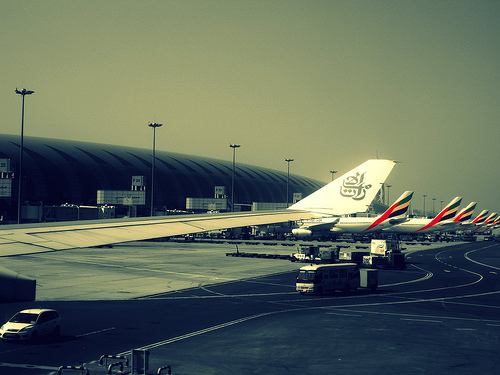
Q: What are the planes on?
A: The tarmac.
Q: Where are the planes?
A: The airport.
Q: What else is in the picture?
A: A bus.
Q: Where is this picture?
A: Airport.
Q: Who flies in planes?
A: Passengers.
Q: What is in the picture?
A: Planes.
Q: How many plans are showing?
A: Seven.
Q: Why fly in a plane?
A: To get where you want faster.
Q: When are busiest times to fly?
A: Holidays.